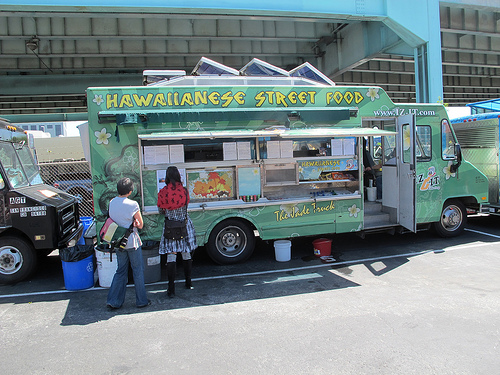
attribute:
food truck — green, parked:
[80, 57, 500, 262]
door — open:
[361, 115, 418, 234]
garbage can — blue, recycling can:
[59, 245, 98, 290]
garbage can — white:
[92, 244, 124, 287]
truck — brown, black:
[1, 119, 83, 281]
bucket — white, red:
[274, 239, 292, 262]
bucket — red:
[311, 238, 333, 257]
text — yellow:
[103, 91, 364, 108]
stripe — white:
[0, 239, 498, 315]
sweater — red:
[154, 181, 189, 210]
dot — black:
[168, 199, 175, 204]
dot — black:
[170, 186, 176, 191]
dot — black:
[158, 191, 163, 199]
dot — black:
[179, 193, 184, 201]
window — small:
[183, 145, 224, 161]